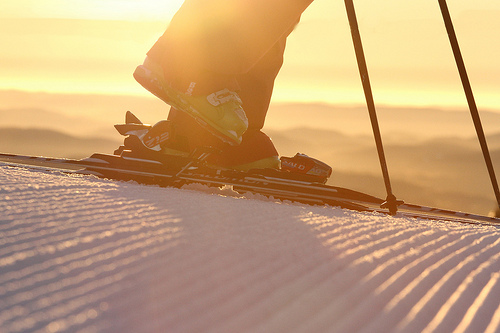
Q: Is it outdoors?
A: Yes, it is outdoors.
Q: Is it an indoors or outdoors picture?
A: It is outdoors.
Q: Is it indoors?
A: No, it is outdoors.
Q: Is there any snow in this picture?
A: Yes, there is snow.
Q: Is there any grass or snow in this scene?
A: Yes, there is snow.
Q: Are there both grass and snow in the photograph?
A: No, there is snow but no grass.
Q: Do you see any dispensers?
A: No, there are no dispensers.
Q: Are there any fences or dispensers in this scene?
A: No, there are no dispensers or fences.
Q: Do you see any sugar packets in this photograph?
A: No, there are no sugar packets.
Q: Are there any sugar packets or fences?
A: No, there are no sugar packets or fences.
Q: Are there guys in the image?
A: No, there are no guys.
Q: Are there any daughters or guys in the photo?
A: No, there are no guys or daughters.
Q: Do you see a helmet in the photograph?
A: No, there are no helmets.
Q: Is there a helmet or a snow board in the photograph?
A: No, there are no helmets or snowboards.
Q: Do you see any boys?
A: No, there are no boys.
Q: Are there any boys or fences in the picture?
A: No, there are no boys or fences.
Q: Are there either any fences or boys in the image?
A: No, there are no boys or fences.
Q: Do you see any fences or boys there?
A: No, there are no boys or fences.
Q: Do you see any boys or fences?
A: No, there are no boys or fences.